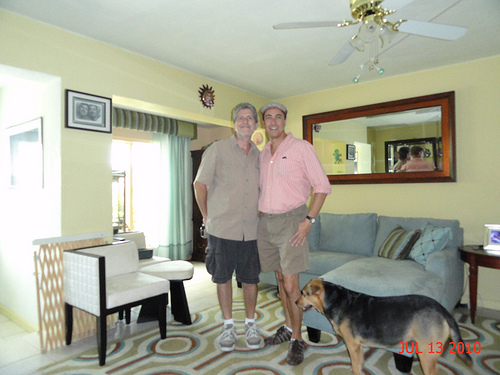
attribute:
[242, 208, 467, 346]
sofa — grey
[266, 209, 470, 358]
couch — grey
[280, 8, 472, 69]
fan — white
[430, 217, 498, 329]
table — round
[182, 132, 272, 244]
shirt — tan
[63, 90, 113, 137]
picture — rectangle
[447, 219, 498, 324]
table — round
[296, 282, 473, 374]
dog — black and tan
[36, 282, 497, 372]
area rug — patterned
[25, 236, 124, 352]
gate — baby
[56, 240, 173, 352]
chair — white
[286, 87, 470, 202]
mirror — Large , rectangular 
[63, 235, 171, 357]
chair — white and black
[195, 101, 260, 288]
man — old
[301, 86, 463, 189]
mirror — rectangle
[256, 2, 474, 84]
ceiling fan — white and gold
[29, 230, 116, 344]
gate — behind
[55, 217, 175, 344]
chair — white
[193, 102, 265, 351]
carpet — large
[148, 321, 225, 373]
carpet — colorful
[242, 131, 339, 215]
shirt — pink